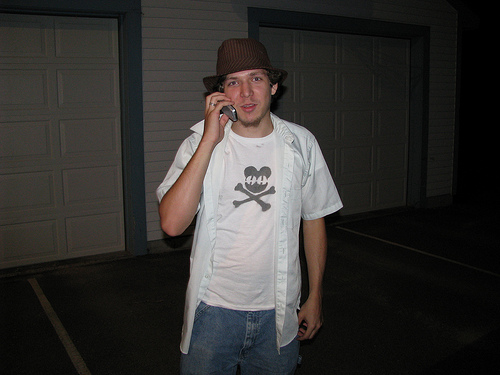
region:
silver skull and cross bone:
[220, 180, 287, 210]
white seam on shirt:
[273, 255, 293, 307]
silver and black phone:
[199, 87, 243, 124]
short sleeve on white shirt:
[301, 195, 351, 227]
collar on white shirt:
[235, 127, 280, 154]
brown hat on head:
[178, 34, 302, 86]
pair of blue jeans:
[181, 283, 328, 361]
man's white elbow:
[136, 207, 224, 249]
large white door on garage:
[305, 50, 401, 123]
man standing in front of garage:
[158, 31, 343, 329]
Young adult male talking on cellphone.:
[155, 38, 343, 373]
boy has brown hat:
[190, 41, 291, 86]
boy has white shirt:
[162, 97, 294, 358]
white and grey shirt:
[185, 131, 310, 328]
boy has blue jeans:
[180, 303, 292, 374]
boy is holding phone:
[194, 87, 265, 161]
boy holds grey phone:
[211, 84, 243, 131]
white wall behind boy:
[155, 18, 220, 116]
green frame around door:
[34, 4, 179, 262]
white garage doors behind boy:
[0, 31, 140, 248]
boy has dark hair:
[175, 54, 315, 139]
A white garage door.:
[0, 13, 126, 268]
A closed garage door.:
[256, 26, 417, 216]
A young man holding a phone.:
[154, 39, 349, 374]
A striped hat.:
[203, 36, 289, 95]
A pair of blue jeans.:
[181, 300, 303, 373]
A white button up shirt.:
[157, 112, 341, 361]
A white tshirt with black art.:
[203, 125, 289, 309]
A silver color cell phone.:
[217, 102, 239, 122]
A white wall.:
[143, 3, 460, 245]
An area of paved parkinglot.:
[0, 200, 499, 371]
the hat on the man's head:
[202, 37, 288, 94]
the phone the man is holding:
[220, 104, 237, 122]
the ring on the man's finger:
[207, 100, 215, 107]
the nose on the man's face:
[239, 80, 253, 97]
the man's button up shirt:
[155, 112, 341, 354]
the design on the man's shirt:
[232, 166, 275, 211]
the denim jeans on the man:
[179, 302, 302, 374]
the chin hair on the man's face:
[237, 115, 262, 128]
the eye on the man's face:
[227, 79, 239, 86]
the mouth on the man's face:
[238, 102, 256, 112]